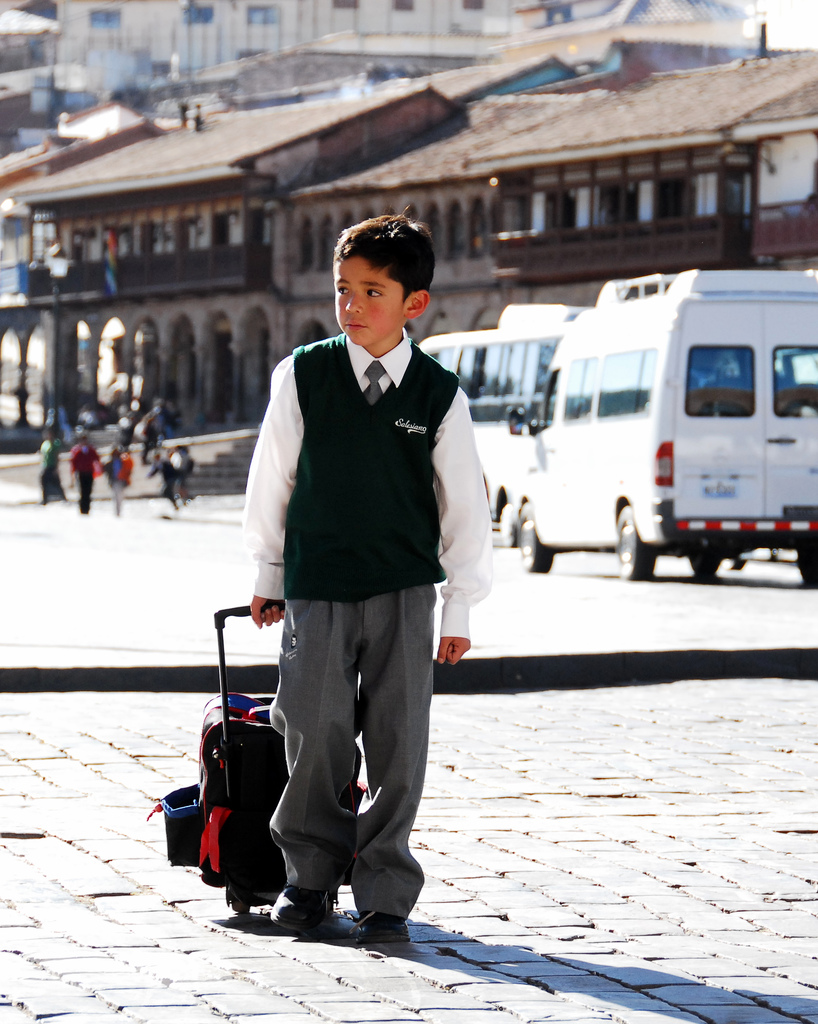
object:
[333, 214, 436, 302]
hair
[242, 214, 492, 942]
boy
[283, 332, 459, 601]
vest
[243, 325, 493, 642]
shirt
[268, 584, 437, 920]
slacks